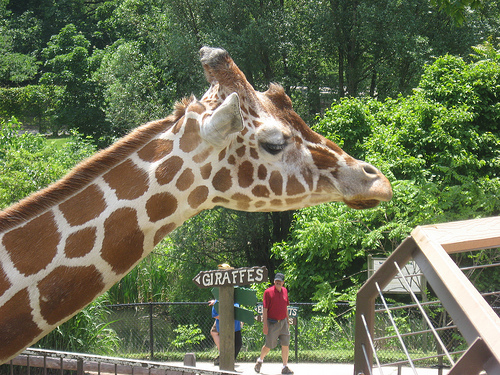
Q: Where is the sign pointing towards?
A: Giraffes.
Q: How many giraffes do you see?
A: 1.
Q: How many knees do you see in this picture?
A: 4.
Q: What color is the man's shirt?
A: Red.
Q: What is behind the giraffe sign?
A: People.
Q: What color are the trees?
A: Green.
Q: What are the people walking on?
A: Path.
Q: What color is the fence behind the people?
A: Black.